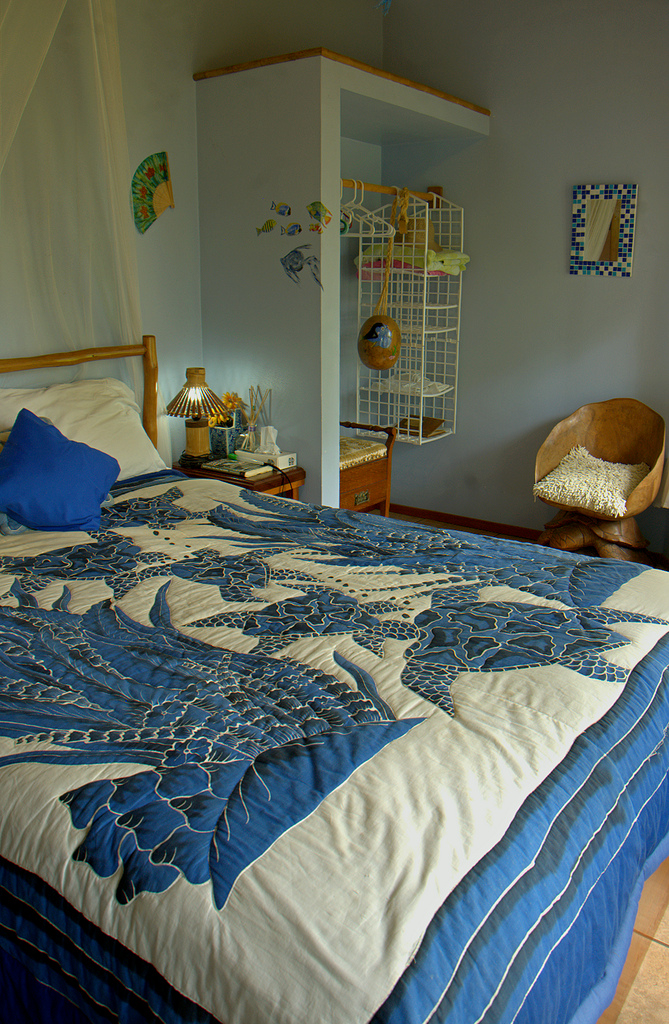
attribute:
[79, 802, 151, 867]
fabric — blue , quilted 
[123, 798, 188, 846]
fabric — blue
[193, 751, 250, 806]
fabric — blue, quilted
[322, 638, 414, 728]
fabric — blue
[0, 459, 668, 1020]
blanket — blue, quilted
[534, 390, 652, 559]
chair — small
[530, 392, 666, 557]
chair — small, wooden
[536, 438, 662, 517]
pillow — white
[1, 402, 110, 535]
pillow — blue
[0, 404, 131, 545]
pillow — square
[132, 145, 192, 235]
fan — green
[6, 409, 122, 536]
pillow — blue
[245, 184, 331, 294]
sticker — fish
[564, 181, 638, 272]
mirror — mosaic tile 